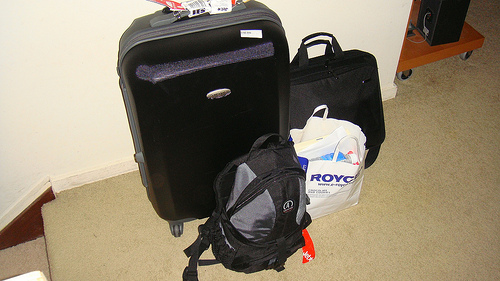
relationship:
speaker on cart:
[415, 1, 470, 47] [398, 22, 485, 79]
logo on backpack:
[282, 200, 295, 214] [183, 134, 312, 281]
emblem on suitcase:
[206, 88, 232, 100] [117, 1, 290, 237]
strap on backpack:
[250, 132, 285, 152] [183, 134, 312, 281]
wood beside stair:
[0, 187, 55, 249] [0, 236, 50, 281]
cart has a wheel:
[398, 22, 485, 79] [398, 69, 413, 81]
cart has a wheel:
[398, 22, 485, 79] [460, 50, 471, 60]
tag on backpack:
[300, 228, 315, 264] [183, 134, 312, 281]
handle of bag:
[291, 33, 342, 67] [289, 32, 385, 168]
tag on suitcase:
[181, 1, 210, 20] [117, 1, 290, 237]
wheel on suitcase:
[169, 220, 184, 239] [117, 1, 290, 237]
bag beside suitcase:
[289, 32, 385, 168] [117, 1, 290, 237]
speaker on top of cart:
[415, 1, 470, 47] [398, 22, 485, 79]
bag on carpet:
[292, 104, 370, 220] [305, 1, 499, 280]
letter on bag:
[311, 173, 320, 181] [289, 32, 385, 168]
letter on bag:
[311, 173, 356, 183] [289, 32, 385, 168]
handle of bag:
[310, 104, 330, 120] [289, 32, 385, 168]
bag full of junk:
[292, 104, 370, 220] [305, 150, 357, 165]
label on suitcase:
[240, 29, 263, 39] [117, 1, 290, 237]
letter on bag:
[311, 173, 320, 181] [292, 104, 370, 220]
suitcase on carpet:
[117, 1, 290, 237] [305, 1, 499, 280]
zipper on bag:
[329, 69, 338, 79] [289, 32, 385, 168]